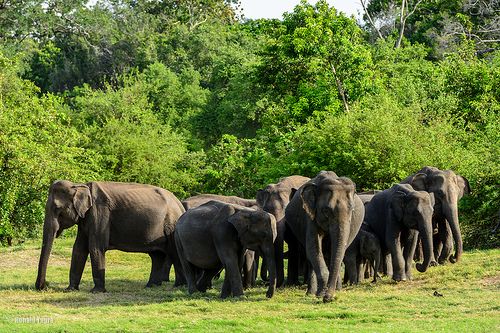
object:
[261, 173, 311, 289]
elephants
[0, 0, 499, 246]
greenery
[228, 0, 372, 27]
sky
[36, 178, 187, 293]
elephant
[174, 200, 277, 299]
elephant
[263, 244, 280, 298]
trunk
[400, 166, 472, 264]
elephant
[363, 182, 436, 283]
elephant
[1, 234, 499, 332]
grass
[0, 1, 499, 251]
background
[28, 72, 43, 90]
leaves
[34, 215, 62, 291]
trunk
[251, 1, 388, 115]
tree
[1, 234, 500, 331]
soil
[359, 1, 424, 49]
branches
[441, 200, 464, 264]
trunk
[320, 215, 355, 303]
trunk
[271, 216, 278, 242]
light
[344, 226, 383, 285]
baby elephant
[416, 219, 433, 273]
trunk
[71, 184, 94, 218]
ear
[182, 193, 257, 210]
elephant